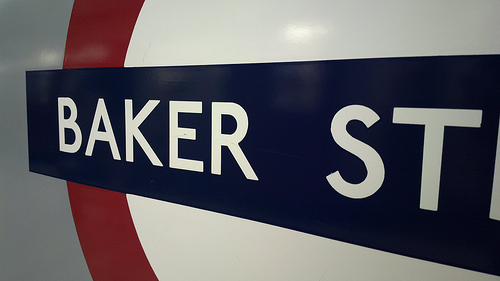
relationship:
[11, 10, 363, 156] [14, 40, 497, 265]
glare on sign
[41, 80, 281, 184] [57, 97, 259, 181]
baker in baker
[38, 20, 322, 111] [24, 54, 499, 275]
glare over blue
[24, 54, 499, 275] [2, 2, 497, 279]
blue on background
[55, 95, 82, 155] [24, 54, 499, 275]
letter on blue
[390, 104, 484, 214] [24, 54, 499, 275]
letter on blue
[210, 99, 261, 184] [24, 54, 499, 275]
letter on blue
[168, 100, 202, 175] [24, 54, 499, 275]
letter on blue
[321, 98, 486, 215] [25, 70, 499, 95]
st on background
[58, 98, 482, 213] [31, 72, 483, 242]
background on background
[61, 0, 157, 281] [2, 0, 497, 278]
circle on white background